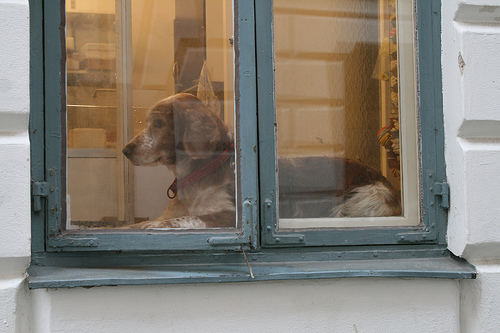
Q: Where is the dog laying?
A: In the window.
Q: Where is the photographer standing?
A: Outside the window.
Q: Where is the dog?
A: Inside the house.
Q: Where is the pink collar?
A: On the dog's neck.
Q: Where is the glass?
A: In the window frames.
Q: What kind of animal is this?
A: Dog.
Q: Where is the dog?
A: In the window.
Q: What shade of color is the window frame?
A: Green.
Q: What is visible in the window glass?
A: Reflections.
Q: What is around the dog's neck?
A: Dog collar.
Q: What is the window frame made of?
A: Metal.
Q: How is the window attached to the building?
A: Hinges.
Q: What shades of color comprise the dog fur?
A: Brown and white.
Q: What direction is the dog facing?
A: Left.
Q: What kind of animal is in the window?
A: Dog.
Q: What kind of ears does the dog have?
A: Floppy.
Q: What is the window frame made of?
A: Metal.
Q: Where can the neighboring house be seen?
A: The reflection in the window.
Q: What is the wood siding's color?
A: White.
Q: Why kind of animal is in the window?
A: Dog.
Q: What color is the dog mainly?
A: Brown.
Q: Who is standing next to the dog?
A: No one.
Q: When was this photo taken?
A: Daytime.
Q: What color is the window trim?
A: Blue.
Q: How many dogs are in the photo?
A: One.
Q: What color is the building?
A: White.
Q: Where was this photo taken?
A: In front of the window.